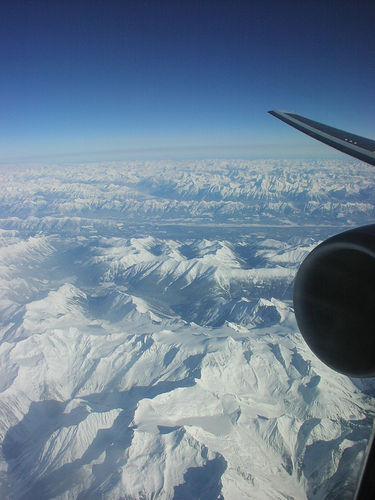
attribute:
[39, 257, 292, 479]
mountain — rocky, jagged 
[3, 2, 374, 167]
sky — blue 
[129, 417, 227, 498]
mountain peak — white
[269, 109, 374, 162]
stripe — light grey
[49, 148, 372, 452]
mountains — sky view